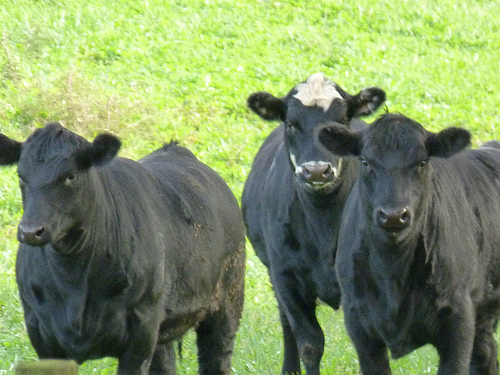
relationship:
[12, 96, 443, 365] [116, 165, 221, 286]
two cows black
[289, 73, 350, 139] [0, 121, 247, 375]
black and white cow between two 3 cows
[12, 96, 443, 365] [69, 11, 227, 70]
three cows in grass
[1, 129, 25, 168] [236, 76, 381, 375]
left ear of a black cow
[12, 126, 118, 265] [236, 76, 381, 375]
head of a black cow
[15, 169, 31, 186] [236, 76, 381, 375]
left eye of a black cow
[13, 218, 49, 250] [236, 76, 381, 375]
nose of a black cow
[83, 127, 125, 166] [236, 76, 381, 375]
right ear of a black cow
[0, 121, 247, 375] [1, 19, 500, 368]
3 cows in field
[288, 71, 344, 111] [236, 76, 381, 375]
white patch of hair on black cow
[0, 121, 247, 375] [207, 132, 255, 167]
3 cows looking forward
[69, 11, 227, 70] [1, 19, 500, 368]
grass in a field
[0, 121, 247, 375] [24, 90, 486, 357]
3 cows standing still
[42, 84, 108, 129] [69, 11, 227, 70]
brown patch of grass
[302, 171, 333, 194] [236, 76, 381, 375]
open mouth of a black cow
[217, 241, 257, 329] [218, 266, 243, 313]
dirt on cow fur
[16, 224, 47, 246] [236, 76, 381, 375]
shiny nose on black cow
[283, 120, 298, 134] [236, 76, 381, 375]
eye of a black cow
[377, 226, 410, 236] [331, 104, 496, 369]
mouth of a cow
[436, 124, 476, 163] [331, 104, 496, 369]
ear of a cow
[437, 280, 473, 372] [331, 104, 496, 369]
leg of a cow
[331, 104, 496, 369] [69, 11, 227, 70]
black cow on grass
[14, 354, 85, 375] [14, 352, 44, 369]
post fence post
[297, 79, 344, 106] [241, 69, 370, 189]
white spot on cow head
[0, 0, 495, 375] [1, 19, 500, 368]
field grassy field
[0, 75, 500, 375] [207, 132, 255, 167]
still facing forward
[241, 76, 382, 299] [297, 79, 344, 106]
black cow with white spot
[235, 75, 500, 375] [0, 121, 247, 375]
two cows black 3 cows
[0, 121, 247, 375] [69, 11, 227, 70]
3 cows standing in grass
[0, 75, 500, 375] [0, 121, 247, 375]
still large 3 cows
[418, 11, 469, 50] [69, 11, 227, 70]
short green grass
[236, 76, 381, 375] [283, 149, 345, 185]
black cow with white markings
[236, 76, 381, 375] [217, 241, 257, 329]
black cow with dirt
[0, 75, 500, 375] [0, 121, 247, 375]
still farm 3 cows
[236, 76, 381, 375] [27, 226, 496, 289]
black cow standing between two cows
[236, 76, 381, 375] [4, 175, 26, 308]
black cow closest to left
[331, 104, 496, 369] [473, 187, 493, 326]
black cow on right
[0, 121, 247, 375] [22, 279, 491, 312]
3 cows of 3 cows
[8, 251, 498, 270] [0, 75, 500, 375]
group of still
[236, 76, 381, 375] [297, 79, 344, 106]
black cow with white spot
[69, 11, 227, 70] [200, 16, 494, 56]
grass in background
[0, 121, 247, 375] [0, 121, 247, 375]
3 cows making 3 cows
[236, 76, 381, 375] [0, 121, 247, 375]
black cow of 3 cows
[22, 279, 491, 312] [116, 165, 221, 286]
3 cows female black